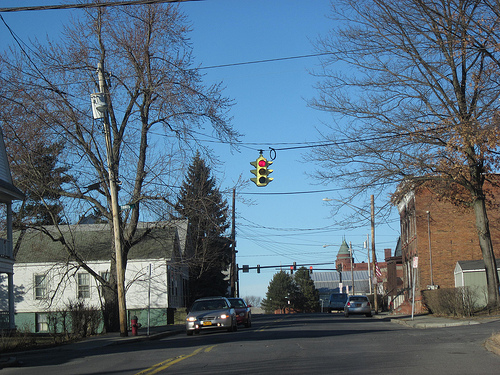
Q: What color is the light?
A: Red.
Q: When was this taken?
A: Daytime.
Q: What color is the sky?
A: Blue.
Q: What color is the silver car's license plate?
A: Yellow.